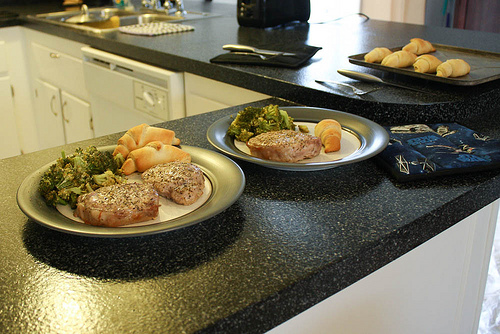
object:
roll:
[312, 117, 343, 154]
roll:
[407, 52, 444, 74]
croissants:
[435, 58, 473, 80]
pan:
[345, 38, 498, 86]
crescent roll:
[110, 122, 184, 160]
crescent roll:
[120, 139, 194, 177]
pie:
[411, 53, 441, 73]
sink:
[27, 5, 207, 32]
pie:
[401, 37, 434, 54]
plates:
[14, 144, 246, 237]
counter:
[17, 0, 499, 121]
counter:
[0, 99, 499, 334]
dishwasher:
[80, 48, 185, 135]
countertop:
[0, 96, 499, 333]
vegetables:
[87, 168, 125, 188]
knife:
[219, 44, 303, 56]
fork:
[232, 51, 288, 62]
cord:
[307, 12, 369, 25]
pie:
[380, 50, 421, 70]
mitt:
[379, 120, 500, 182]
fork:
[314, 80, 385, 96]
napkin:
[209, 37, 321, 69]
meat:
[72, 178, 161, 229]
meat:
[140, 158, 203, 207]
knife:
[336, 68, 427, 94]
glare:
[15, 251, 104, 327]